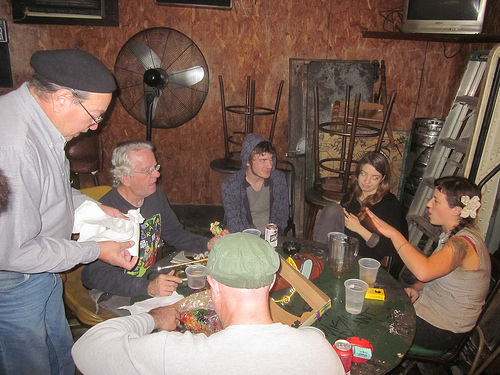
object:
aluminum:
[270, 229, 278, 245]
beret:
[27, 45, 123, 97]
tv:
[396, 1, 487, 40]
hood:
[238, 132, 279, 172]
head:
[109, 142, 160, 197]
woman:
[313, 148, 410, 281]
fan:
[109, 24, 210, 141]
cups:
[344, 277, 369, 316]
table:
[128, 231, 419, 375]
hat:
[204, 229, 281, 289]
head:
[425, 174, 482, 224]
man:
[219, 131, 281, 241]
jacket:
[217, 131, 291, 237]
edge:
[380, 306, 420, 373]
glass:
[335, 247, 347, 259]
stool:
[208, 74, 284, 175]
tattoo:
[446, 236, 470, 274]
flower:
[459, 195, 481, 217]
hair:
[432, 173, 482, 239]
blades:
[166, 66, 207, 87]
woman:
[366, 175, 496, 352]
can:
[264, 222, 282, 249]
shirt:
[340, 186, 410, 282]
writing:
[309, 305, 376, 341]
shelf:
[359, 30, 500, 43]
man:
[0, 47, 145, 373]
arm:
[389, 226, 465, 282]